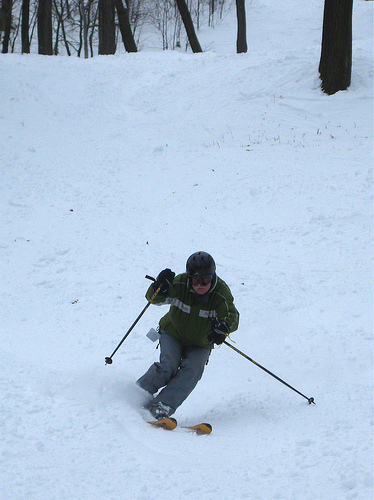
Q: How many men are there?
A: One.